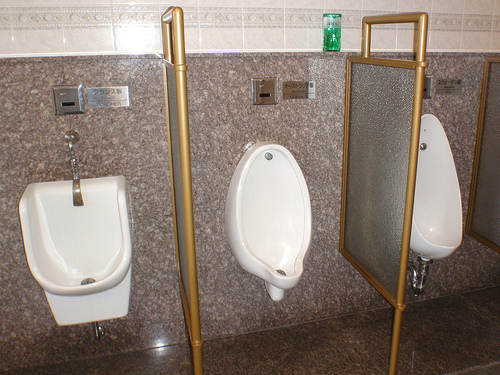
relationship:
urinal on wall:
[408, 113, 466, 268] [2, 2, 499, 372]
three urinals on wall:
[17, 110, 468, 327] [2, 2, 499, 372]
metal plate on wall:
[83, 78, 135, 112] [2, 2, 499, 372]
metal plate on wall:
[431, 73, 466, 98] [2, 2, 499, 372]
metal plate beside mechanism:
[83, 78, 135, 112] [48, 81, 88, 119]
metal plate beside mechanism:
[281, 78, 320, 103] [252, 74, 281, 107]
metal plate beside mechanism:
[431, 73, 466, 98] [421, 72, 436, 100]